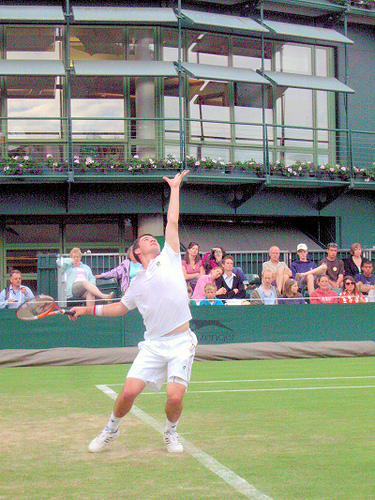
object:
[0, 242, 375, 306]
fans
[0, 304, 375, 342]
stand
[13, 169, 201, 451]
tennis player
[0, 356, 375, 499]
court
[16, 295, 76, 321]
racket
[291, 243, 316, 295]
fan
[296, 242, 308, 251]
hat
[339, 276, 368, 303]
woman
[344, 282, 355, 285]
sunglasses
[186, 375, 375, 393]
lines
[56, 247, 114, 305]
woman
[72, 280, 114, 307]
legs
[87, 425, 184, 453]
shoes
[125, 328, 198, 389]
shorts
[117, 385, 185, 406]
knees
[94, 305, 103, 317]
wrist band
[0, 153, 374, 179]
flowers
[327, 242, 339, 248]
sunglasses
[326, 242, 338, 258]
head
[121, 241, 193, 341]
shirt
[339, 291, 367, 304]
shirt